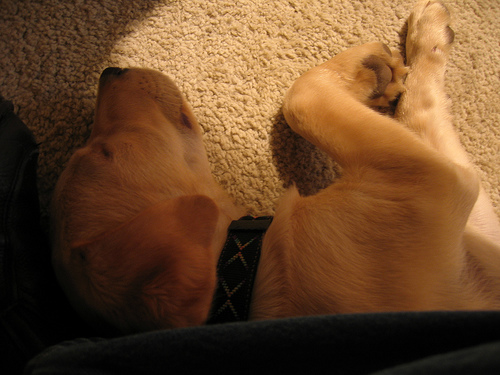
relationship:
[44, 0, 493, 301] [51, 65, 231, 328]
dog has nose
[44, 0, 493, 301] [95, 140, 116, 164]
dog has eye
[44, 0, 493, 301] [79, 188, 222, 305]
dog has ear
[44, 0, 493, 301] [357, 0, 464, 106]
dog has paw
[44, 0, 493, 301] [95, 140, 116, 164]
dog has eyes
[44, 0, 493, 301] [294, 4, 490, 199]
dog has legs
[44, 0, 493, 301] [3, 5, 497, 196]
dog on floor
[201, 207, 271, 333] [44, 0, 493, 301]
collar on dog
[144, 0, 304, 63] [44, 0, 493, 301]
carpet next to dog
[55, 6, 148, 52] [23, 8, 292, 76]
shadow on ground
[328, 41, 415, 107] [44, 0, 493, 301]
dog's paw on dog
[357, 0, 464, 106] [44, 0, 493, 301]
paw on dog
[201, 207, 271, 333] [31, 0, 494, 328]
collar on dog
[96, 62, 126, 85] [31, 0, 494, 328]
nose on dog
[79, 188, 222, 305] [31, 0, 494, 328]
ear on dog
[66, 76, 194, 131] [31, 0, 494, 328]
whiskers are on dog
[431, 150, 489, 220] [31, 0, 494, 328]
elbow on dog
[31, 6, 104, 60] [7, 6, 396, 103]
shadow on carpet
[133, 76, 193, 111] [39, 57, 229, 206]
whiskers are on dog's face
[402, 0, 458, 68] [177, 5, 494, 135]
paw on carpet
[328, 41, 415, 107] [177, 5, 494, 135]
dog's paw on carpet